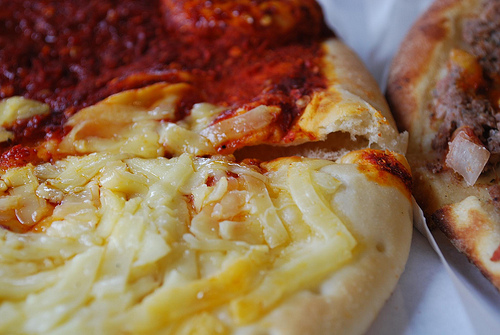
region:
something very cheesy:
[0, 159, 401, 296]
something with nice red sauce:
[30, 0, 348, 170]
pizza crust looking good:
[60, 0, 399, 301]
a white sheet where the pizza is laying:
[351, 13, 411, 63]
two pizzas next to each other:
[4, 1, 499, 304]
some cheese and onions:
[285, 164, 387, 296]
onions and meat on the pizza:
[443, 121, 498, 183]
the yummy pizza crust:
[289, 95, 377, 146]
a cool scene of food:
[4, 10, 498, 325]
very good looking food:
[8, 14, 498, 322]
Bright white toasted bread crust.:
[326, 157, 418, 300]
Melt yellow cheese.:
[45, 30, 412, 333]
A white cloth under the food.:
[332, 19, 469, 332]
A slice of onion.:
[439, 135, 486, 182]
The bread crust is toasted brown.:
[403, 48, 494, 265]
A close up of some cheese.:
[65, 155, 165, 243]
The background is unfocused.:
[38, 5, 372, 144]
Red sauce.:
[78, 14, 347, 118]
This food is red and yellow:
[38, 28, 356, 291]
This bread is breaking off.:
[218, 109, 377, 193]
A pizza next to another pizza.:
[41, 17, 491, 296]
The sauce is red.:
[85, 40, 238, 71]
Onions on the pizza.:
[431, 88, 482, 206]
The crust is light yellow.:
[322, 62, 376, 273]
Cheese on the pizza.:
[102, 183, 257, 278]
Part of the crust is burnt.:
[361, 106, 405, 203]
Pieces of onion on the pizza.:
[422, 91, 478, 188]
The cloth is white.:
[416, 252, 481, 332]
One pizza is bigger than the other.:
[132, 6, 459, 277]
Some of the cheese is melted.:
[112, 210, 296, 297]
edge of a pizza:
[393, 186, 413, 236]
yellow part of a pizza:
[297, 204, 320, 247]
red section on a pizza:
[233, 83, 280, 89]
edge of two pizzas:
[371, 137, 449, 216]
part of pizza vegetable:
[156, 170, 217, 219]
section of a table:
[386, 285, 436, 327]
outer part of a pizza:
[358, 200, 380, 212]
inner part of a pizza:
[213, 157, 276, 205]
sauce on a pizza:
[161, 35, 227, 123]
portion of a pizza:
[304, 97, 339, 165]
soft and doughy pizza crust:
[275, 46, 422, 203]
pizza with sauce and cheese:
[2, 132, 344, 320]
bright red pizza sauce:
[9, 0, 407, 148]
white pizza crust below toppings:
[272, 14, 439, 329]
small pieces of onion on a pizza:
[429, 116, 493, 225]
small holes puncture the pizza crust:
[271, 186, 422, 330]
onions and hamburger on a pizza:
[426, 0, 495, 200]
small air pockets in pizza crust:
[230, 93, 405, 183]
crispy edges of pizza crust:
[366, 0, 466, 226]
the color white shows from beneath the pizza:
[296, 0, 491, 327]